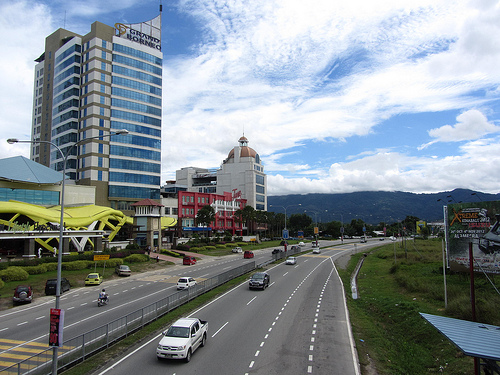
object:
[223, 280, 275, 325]
truck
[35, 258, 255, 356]
fence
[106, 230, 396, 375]
road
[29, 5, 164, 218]
building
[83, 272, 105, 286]
cars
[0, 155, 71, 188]
shed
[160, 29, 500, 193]
sky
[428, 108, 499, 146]
clouds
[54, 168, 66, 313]
pole